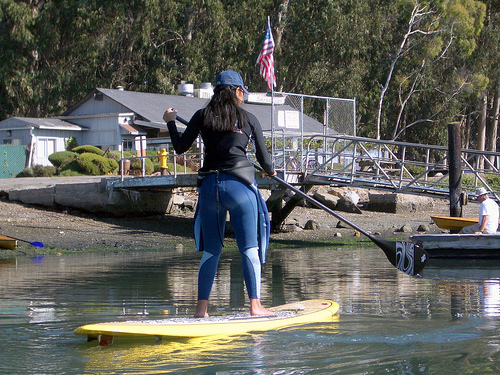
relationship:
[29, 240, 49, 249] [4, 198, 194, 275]
oar on shore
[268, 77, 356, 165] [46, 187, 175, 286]
fence on shore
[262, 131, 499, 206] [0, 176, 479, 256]
bridge to dock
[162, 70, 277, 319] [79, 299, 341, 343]
lady up paddle board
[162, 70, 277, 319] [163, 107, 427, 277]
lady with oar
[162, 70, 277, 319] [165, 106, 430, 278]
lady holding stick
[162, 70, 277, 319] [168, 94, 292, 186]
lady wearing black swimwear shirt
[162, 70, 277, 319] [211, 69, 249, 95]
lady wearing a blue cap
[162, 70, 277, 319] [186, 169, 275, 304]
lady wearing a wet suit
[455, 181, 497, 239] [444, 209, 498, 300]
man sitting in boat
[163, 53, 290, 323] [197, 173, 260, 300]
lady wearing blue wetsuit